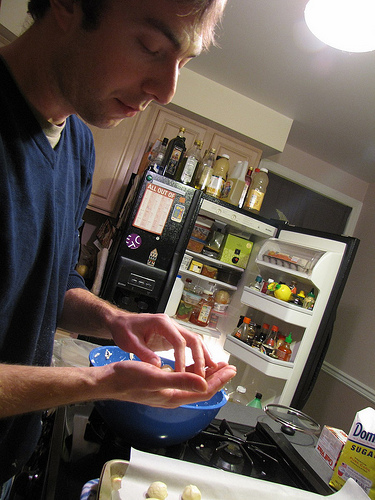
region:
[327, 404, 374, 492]
bag of domino sugar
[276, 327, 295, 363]
bottle of red sauce in green bottle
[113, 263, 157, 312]
black water and ice dispenser in refrigerator door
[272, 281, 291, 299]
yellow lemon ball with green top in refrigerator door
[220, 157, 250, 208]
bottom of oil in large clear bottle with white top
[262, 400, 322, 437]
clear glass pot top with black knob on top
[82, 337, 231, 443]
blue metal bowl on stove top burner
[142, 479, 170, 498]
white ball of dough on white paper on tin pan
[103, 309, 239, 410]
two hands kneading white dough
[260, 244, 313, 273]
grey carton of 12 dozen eggs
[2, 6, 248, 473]
Man in kitchen making cookies.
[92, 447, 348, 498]
Cookie balls on cooking tray.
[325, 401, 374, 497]
Yellow and white bag of sugar.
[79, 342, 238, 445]
Blue plastic bag with cookie dough mixture.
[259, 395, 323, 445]
Top to pot lying on kitchen counter.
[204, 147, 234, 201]
Bottle of grapefruit juice on top of refrigerator.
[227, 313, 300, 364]
Assortment of bottles on refregerator door.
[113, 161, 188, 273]
Paper and magnets on refrigerator door.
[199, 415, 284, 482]
Back burner on top of stove.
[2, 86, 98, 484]
Man dressed in navy blue vee neck t-shirt.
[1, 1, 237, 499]
man making sugar cookies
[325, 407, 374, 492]
bag of Domino brand sugar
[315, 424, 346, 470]
box of Great Value butter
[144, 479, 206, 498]
rolled cookie dough on parchment paper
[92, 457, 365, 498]
parchment paper lined cookie sheet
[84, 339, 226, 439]
blue plastic bowl with dough in it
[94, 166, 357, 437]
black fridge with door open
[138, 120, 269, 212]
juice, oil, and liquor bottles on top of fridge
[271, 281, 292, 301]
yellow plastic lemon juice container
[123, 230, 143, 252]
white and purple fridge magnet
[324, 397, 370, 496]
sugar is behind the stove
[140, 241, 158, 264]
a magnet is on the black frigerator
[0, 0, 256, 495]
a man is standing over the stove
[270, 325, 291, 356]
Sriracha sauce is in the frigerator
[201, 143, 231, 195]
a container of juice is on top of the refrigerator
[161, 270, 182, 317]
milk is inside the frigerator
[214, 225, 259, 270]
a box of wine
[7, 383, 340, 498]
a black stove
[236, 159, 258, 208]
a bottle of wine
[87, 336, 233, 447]
a blue bowl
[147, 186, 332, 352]
the fridge is black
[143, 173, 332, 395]
the fridge is open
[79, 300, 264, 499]
the man is making cookies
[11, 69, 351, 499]
he is in the kitchen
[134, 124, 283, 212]
the liquor bottles are on top of the fridge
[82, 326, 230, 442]
the big bowl is on the stove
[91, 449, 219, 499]
the pan has cookies on it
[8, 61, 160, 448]
the is wearing a blue shirt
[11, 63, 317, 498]
the man is cooking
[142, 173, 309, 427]
the fridge is full